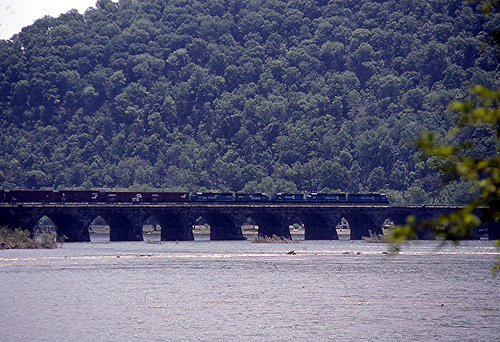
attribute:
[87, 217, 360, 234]
shoreline — sandy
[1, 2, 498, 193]
hill — covered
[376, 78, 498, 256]
leaves — green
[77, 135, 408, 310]
bridge — dark gray, stone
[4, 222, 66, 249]
bushes — small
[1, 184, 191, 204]
cargo cars — reddish brown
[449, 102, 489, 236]
leaves — greenish-yellow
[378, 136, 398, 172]
tree — lush, green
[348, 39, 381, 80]
tree — lush, green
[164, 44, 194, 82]
tree — lush, green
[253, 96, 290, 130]
tree — lush, green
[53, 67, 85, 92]
tree — lush, green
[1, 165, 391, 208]
train — blue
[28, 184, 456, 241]
bridge — stone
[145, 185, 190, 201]
car — red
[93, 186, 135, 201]
car — red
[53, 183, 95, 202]
car — red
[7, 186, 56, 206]
car — red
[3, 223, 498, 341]
water — gray